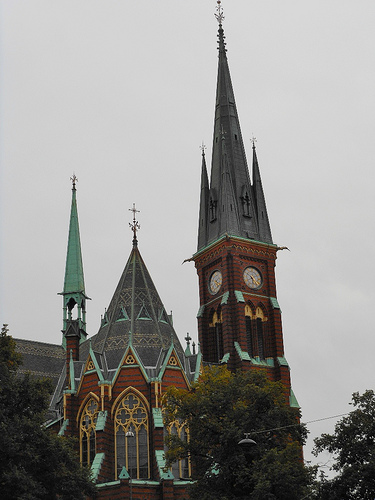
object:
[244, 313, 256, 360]
window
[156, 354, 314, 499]
tree top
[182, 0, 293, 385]
tower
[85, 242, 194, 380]
roof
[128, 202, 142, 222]
cross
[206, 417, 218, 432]
branch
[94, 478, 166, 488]
edge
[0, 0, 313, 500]
building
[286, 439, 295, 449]
leaf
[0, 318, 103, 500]
tree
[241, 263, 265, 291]
clock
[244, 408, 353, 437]
power line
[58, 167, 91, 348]
spire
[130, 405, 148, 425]
circle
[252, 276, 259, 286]
hand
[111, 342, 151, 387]
triangle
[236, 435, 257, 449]
lamp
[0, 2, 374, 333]
sky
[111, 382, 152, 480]
window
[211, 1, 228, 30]
weather vane